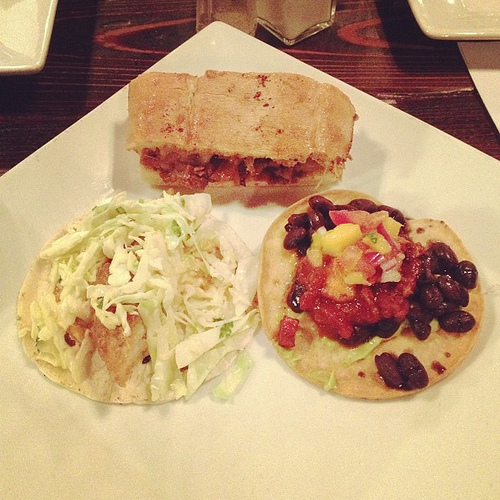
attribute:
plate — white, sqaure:
[54, 130, 476, 500]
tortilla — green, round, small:
[49, 212, 225, 410]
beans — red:
[310, 219, 455, 374]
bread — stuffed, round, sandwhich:
[127, 77, 359, 182]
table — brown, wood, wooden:
[73, 11, 130, 61]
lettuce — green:
[116, 229, 191, 301]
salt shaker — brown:
[269, 10, 342, 44]